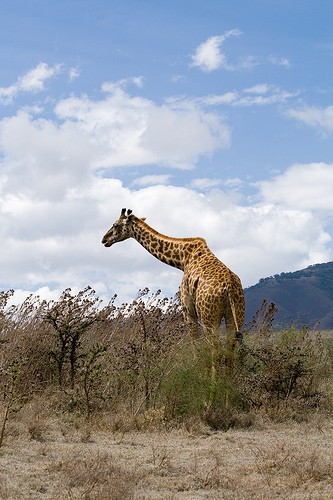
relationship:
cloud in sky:
[0, 0, 333, 317] [0, 1, 329, 321]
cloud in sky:
[0, 0, 333, 317] [2, 28, 330, 263]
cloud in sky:
[0, 0, 333, 317] [125, 18, 170, 50]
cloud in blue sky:
[0, 0, 333, 317] [0, 0, 333, 312]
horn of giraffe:
[120, 203, 126, 216] [101, 206, 245, 408]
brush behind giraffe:
[166, 348, 245, 414] [101, 206, 245, 408]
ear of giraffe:
[124, 213, 133, 225] [101, 206, 245, 408]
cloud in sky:
[0, 0, 333, 317] [1, 1, 331, 268]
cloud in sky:
[192, 31, 291, 73] [0, 1, 329, 321]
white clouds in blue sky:
[34, 107, 206, 204] [29, 8, 172, 49]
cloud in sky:
[0, 0, 333, 317] [0, 0, 188, 52]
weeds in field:
[0, 280, 330, 433] [1, 318, 332, 498]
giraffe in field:
[101, 207, 247, 423] [80, 355, 201, 436]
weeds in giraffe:
[0, 280, 331, 423] [101, 206, 245, 408]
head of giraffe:
[97, 207, 150, 256] [60, 195, 278, 391]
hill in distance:
[242, 248, 332, 323] [234, 139, 330, 376]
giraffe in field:
[101, 207, 247, 423] [39, 311, 327, 455]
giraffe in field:
[101, 207, 247, 423] [18, 314, 272, 438]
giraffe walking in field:
[108, 206, 270, 356] [59, 374, 269, 458]